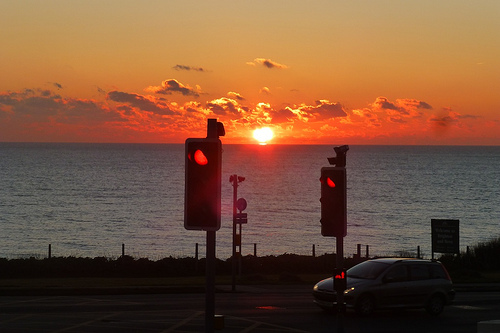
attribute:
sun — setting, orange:
[248, 123, 279, 148]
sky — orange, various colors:
[2, 3, 498, 147]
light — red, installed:
[193, 147, 212, 166]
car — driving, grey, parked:
[313, 255, 457, 317]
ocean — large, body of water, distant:
[2, 146, 500, 251]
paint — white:
[449, 304, 491, 313]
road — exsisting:
[0, 291, 496, 332]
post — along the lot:
[120, 243, 126, 260]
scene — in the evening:
[4, 1, 499, 332]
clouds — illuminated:
[2, 55, 488, 141]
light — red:
[311, 284, 319, 293]